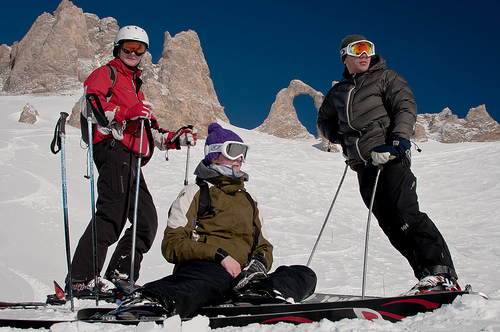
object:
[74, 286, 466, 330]
ski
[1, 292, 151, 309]
ski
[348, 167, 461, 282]
pants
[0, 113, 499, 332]
snow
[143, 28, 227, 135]
mountain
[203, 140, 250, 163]
goggles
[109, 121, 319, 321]
man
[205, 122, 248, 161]
purple toboggan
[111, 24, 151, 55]
helmet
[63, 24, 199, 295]
man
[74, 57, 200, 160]
jacket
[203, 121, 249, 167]
purple hat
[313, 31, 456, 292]
man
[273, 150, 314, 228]
ground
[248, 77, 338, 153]
archway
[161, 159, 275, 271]
jacket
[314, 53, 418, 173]
jacket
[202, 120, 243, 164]
beanie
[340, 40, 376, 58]
goggles